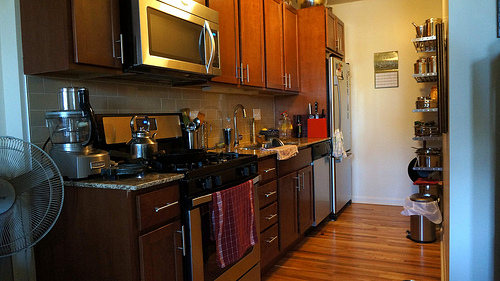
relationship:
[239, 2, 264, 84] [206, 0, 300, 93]
door for cabinet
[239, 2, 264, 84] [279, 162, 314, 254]
door for cabinet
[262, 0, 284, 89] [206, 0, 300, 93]
door for cabinet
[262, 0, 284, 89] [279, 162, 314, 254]
door for cabinet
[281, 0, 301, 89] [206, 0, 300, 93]
door for cabinet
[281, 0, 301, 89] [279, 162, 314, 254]
door for cabinet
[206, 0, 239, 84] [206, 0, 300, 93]
door for cabinet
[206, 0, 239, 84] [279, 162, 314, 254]
door for cabinet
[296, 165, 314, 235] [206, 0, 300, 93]
door for cabinet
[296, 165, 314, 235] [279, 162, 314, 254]
door for cabinet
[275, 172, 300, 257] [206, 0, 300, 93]
door for cabinet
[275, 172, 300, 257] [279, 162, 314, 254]
door for cabinet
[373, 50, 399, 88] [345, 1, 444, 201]
calendar on wall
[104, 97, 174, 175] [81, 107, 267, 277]
kettle on stovetop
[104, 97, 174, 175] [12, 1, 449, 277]
kettle in kitchen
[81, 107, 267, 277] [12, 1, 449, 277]
stovetop in kitchen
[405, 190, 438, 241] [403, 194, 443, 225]
trash bin with bag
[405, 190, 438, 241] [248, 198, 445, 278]
trash bin on floor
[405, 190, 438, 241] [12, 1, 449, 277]
trash bin in kitchen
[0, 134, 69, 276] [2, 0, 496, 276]
fan in kitchen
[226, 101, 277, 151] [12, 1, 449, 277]
faucet in kitchen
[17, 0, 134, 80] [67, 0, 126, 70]
cabinet has door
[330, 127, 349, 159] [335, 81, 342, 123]
towel hanging from refrigerator handle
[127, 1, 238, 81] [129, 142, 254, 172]
microwave oven above stovetop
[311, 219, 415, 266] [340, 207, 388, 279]
panels on floor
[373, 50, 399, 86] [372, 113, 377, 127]
calendar on wall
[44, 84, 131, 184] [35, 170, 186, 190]
processor on countertop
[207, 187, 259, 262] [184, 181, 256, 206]
dish towel on oven handle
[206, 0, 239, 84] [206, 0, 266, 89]
door covering cabinet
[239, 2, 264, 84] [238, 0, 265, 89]
door covering cabinet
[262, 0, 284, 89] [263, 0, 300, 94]
door covering cabinet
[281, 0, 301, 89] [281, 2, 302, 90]
door covering cabinet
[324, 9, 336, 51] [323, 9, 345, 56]
door covering cabinet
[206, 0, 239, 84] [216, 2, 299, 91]
door covering cabinet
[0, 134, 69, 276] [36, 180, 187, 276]
fan standing next to cabinet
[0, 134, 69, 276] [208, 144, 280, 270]
fan standing next to cabinet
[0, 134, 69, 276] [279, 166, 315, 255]
fan standing next to cabinet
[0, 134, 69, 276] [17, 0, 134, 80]
fan standing next to cabinet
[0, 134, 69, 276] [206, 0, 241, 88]
fan standing next to cabinet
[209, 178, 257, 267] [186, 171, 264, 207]
dish towel hanging from oven handle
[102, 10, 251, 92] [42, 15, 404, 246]
microwave oven mounted in kitchen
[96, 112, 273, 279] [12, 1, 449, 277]
oven standing in kitchen